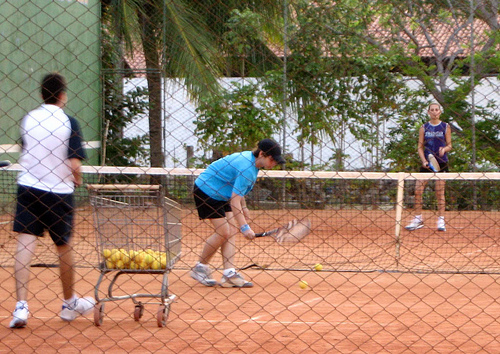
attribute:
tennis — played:
[97, 178, 393, 319]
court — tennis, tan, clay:
[10, 185, 485, 340]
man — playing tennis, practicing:
[180, 128, 299, 276]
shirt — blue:
[205, 143, 256, 223]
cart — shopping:
[65, 201, 193, 311]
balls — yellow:
[100, 241, 175, 275]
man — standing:
[13, 71, 83, 322]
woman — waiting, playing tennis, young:
[408, 104, 453, 245]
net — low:
[8, 151, 497, 273]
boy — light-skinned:
[188, 124, 299, 291]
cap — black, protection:
[251, 129, 289, 171]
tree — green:
[99, 2, 283, 177]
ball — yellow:
[290, 260, 323, 296]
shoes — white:
[0, 284, 108, 332]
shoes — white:
[412, 205, 446, 243]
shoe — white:
[430, 210, 465, 233]